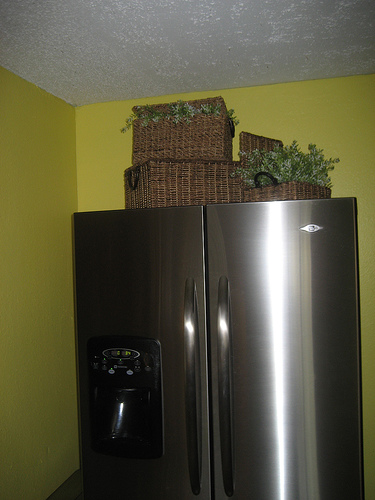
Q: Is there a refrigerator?
A: Yes, there is a refrigerator.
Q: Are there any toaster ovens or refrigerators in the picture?
A: Yes, there is a refrigerator.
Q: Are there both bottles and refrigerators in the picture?
A: No, there is a refrigerator but no bottles.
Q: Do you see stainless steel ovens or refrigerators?
A: Yes, there is a stainless steel refrigerator.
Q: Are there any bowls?
A: No, there are no bowls.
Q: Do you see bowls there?
A: No, there are no bowls.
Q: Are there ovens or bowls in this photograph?
A: No, there are no bowls or ovens.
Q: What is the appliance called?
A: The appliance is a refrigerator.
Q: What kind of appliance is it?
A: The appliance is a refrigerator.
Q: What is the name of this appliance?
A: This is a refrigerator.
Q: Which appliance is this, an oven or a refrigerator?
A: This is a refrigerator.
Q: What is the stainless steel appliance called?
A: The appliance is a refrigerator.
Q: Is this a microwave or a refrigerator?
A: This is a refrigerator.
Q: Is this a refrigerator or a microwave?
A: This is a refrigerator.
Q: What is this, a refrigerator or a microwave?
A: This is a refrigerator.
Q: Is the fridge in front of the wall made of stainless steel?
A: Yes, the refrigerator is made of stainless steel.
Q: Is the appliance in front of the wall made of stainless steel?
A: Yes, the refrigerator is made of stainless steel.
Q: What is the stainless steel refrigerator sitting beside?
A: The refrigerator is sitting beside the wall.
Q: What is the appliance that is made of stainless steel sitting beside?
A: The refrigerator is sitting beside the wall.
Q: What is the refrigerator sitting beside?
A: The refrigerator is sitting beside the wall.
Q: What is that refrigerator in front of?
A: The refrigerator is in front of the wall.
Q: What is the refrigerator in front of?
A: The refrigerator is in front of the wall.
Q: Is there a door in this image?
A: Yes, there is a door.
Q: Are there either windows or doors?
A: Yes, there is a door.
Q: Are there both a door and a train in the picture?
A: No, there is a door but no trains.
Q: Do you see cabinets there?
A: No, there are no cabinets.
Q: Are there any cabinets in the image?
A: No, there are no cabinets.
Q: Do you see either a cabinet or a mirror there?
A: No, there are no cabinets or mirrors.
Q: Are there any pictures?
A: No, there are no pictures.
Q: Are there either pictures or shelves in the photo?
A: No, there are no pictures or shelves.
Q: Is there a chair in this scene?
A: No, there are no chairs.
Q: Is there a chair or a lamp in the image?
A: No, there are no chairs or lamps.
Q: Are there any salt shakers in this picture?
A: No, there are no salt shakers.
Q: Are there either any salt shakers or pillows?
A: No, there are no salt shakers or pillows.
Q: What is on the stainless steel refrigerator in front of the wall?
A: The basket is on the refrigerator.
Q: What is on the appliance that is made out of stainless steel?
A: The basket is on the refrigerator.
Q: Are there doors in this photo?
A: Yes, there is a door.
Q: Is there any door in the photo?
A: Yes, there is a door.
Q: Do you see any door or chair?
A: Yes, there is a door.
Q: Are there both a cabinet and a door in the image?
A: No, there is a door but no cabinets.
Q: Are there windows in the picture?
A: No, there are no windows.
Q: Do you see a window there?
A: No, there are no windows.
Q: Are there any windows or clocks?
A: No, there are no windows or clocks.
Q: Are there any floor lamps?
A: No, there are no floor lamps.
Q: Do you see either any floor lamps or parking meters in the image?
A: No, there are no floor lamps or parking meters.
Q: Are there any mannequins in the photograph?
A: No, there are no mannequins.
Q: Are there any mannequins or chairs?
A: No, there are no mannequins or chairs.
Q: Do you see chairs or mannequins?
A: No, there are no mannequins or chairs.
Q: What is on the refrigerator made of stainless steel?
A: The basket is on the fridge.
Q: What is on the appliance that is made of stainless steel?
A: The basket is on the fridge.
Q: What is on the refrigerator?
A: The basket is on the fridge.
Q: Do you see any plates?
A: No, there are no plates.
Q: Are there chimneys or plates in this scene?
A: No, there are no plates or chimneys.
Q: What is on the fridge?
A: The basket is on the fridge.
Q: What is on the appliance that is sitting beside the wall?
A: The basket is on the fridge.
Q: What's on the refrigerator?
A: The basket is on the fridge.